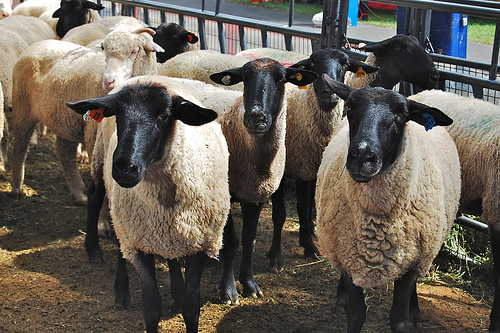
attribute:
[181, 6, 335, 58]
rail — metal, black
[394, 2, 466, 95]
post — blue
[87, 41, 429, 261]
sheep — looking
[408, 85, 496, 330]
sheep — flock 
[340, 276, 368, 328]
leg — black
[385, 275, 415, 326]
leg — black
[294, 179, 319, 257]
leg — black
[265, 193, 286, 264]
leg — black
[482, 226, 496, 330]
leg — black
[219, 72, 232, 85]
tag — yellow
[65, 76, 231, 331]
sheep — white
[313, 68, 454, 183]
head — white, black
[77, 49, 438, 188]
heads — black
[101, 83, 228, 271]
wool — white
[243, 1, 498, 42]
grass — short, green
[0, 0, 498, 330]
flock — sheep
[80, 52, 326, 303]
sheep — white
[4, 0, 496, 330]
herd — small, sheep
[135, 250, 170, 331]
leg — black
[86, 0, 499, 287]
fence — black, metal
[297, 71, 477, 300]
sheep — reacting, four, attentive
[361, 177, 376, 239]
fleece — tan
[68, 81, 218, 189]
head — black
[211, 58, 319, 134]
head — black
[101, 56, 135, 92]
snout — white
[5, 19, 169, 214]
sheep — white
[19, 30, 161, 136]
fur — white